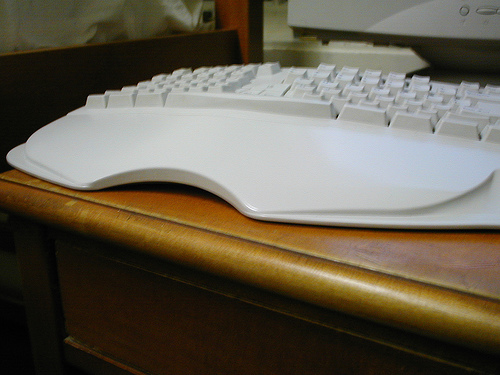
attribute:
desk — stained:
[4, 167, 499, 373]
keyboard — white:
[5, 58, 498, 228]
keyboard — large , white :
[54, 65, 438, 200]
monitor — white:
[286, 0, 498, 72]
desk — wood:
[0, 66, 500, 373]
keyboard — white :
[15, 21, 499, 232]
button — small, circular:
[455, 4, 472, 20]